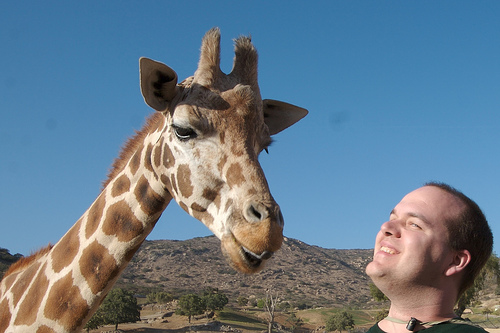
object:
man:
[363, 179, 494, 332]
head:
[364, 181, 495, 296]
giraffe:
[0, 27, 308, 332]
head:
[136, 26, 311, 276]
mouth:
[231, 232, 281, 275]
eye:
[168, 120, 199, 143]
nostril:
[240, 197, 271, 227]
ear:
[139, 56, 182, 112]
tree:
[173, 283, 209, 324]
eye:
[407, 221, 426, 230]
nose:
[379, 216, 404, 239]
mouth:
[373, 240, 403, 259]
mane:
[103, 111, 170, 189]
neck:
[10, 168, 174, 307]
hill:
[188, 249, 384, 312]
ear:
[443, 247, 471, 278]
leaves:
[170, 291, 193, 317]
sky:
[303, 19, 500, 165]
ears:
[139, 56, 180, 113]